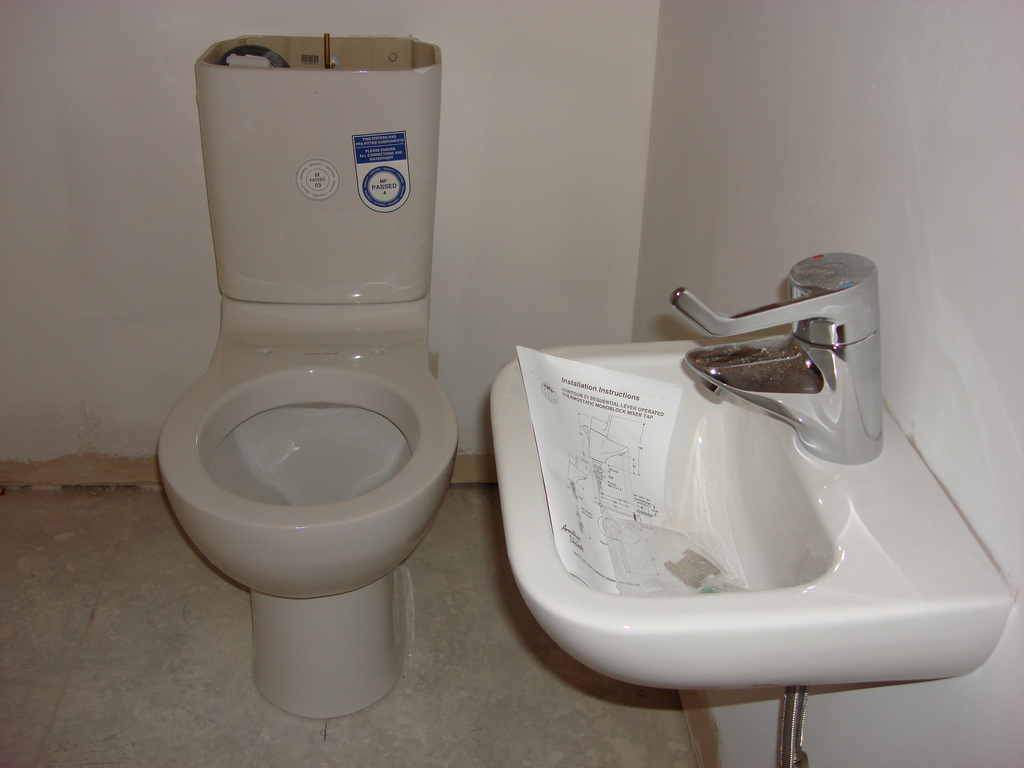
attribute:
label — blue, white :
[348, 111, 431, 218]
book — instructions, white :
[504, 325, 738, 624]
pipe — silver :
[776, 666, 822, 764]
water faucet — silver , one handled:
[632, 234, 909, 459]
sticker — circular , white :
[282, 145, 349, 208]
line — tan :
[29, 575, 146, 764]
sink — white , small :
[476, 236, 1010, 714]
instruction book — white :
[508, 320, 737, 627]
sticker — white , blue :
[331, 102, 435, 223]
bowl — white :
[169, 342, 429, 563]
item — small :
[659, 530, 722, 587]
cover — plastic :
[588, 487, 753, 591]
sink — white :
[497, 340, 1018, 710]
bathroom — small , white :
[9, 5, 1018, 760]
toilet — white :
[176, 18, 453, 654]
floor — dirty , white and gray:
[4, 448, 728, 755]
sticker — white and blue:
[350, 119, 417, 213]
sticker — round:
[294, 158, 344, 206]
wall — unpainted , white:
[8, 7, 659, 476]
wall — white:
[631, 5, 1018, 764]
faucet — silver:
[667, 251, 896, 468]